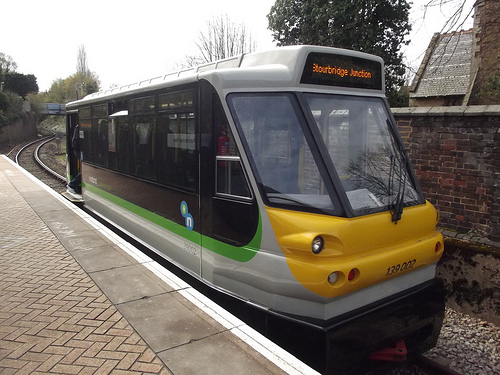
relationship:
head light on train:
[307, 230, 327, 260] [190, 30, 407, 257]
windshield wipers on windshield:
[318, 114, 427, 231] [241, 83, 408, 225]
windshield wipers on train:
[318, 114, 427, 231] [77, 41, 422, 263]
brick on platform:
[1, 174, 168, 372] [0, 155, 317, 372]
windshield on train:
[236, 92, 424, 210] [49, 40, 459, 361]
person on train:
[67, 120, 84, 195] [64, 42, 444, 353]